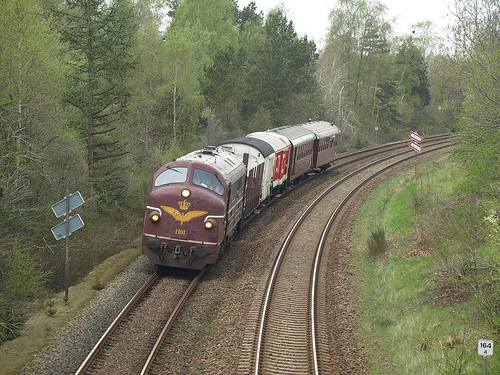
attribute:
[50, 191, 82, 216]
sign — slanted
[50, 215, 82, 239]
sign — slanted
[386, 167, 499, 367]
grass — green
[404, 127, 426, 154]
signs — black, white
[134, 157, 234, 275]
train — purple, yellow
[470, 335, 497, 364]
sign — black, white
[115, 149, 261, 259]
cart — brown, small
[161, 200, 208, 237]
design — yellow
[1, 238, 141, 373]
grass — green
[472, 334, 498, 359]
sign — small, white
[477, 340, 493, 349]
lettering — black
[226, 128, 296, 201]
car — second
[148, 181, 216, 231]
lights — glowing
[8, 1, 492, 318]
area — wooded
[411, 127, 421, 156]
signs — white, red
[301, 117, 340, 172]
cart — small, brown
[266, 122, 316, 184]
cart — small, brown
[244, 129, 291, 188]
cart — small, brown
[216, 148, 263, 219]
cart — small, brown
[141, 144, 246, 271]
cart — small, brown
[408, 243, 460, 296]
grass — green, small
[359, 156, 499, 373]
grass — small, green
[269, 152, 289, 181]
lettering — red